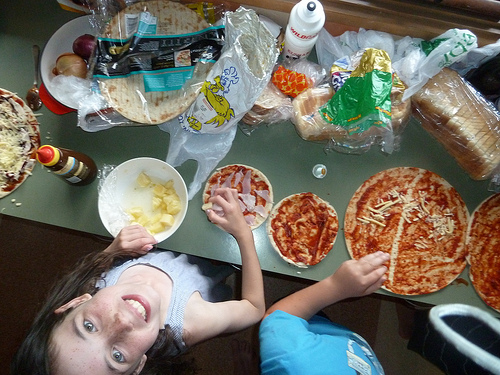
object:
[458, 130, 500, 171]
bread`s slices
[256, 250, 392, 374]
child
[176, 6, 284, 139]
bags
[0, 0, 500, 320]
counter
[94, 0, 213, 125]
pita bread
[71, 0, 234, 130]
plastic wrapping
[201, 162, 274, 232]
tortilla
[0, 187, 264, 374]
girl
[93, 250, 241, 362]
top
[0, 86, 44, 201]
food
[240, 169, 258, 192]
toppings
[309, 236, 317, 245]
tomato sauce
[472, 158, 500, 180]
bread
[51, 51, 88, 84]
onions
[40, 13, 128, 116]
bowl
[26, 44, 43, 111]
spoon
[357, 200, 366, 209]
sauce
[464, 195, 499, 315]
pizza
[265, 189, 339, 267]
cheese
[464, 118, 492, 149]
loaves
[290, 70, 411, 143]
loaves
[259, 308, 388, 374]
top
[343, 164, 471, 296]
pizza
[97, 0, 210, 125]
tortilla